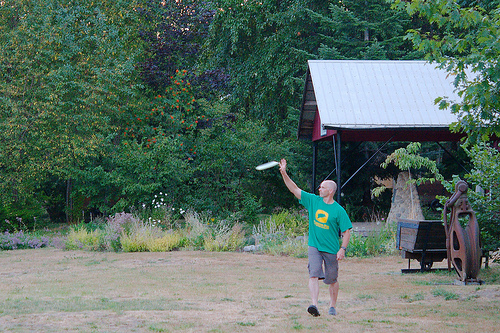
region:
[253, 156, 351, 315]
A man catching a frisbee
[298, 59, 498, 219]
An old red barn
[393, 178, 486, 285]
A piece of old farm equipment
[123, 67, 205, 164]
a tree with red flowers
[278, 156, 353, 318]
a man in a green shirt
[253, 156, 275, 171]
a white frisbee flying through the air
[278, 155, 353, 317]
a man playing a game of catch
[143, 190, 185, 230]
a bush with white flowers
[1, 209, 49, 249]
a bush with purple flowers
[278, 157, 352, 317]
a man playing a game in a field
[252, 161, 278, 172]
White frisbee in the air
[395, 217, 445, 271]
Old wooden cart with metal trim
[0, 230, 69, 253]
Purple flowers on the ground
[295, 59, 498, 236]
Large shed in the background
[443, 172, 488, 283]
Old rusted metal wheel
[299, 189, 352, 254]
Green t-shirt with yellow print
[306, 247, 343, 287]
Grey shorts on a man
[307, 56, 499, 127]
White metal roof on a shed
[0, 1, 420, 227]
Tall trees in the background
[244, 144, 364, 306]
man catching a frisbee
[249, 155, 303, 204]
the frisbee is white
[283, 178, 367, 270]
shirt is green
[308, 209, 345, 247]
letters are yellow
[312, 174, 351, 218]
man has no hair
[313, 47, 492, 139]
roof is white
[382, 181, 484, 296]
old trailer made of wood and iron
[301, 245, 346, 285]
the mans shorts are gray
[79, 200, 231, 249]
tall grass behind the man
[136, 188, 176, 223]
white flowers on the grass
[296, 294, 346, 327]
man is wearing shoes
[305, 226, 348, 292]
man is wearing gray shorts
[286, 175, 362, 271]
the man is wearing a green shirt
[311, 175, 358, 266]
man is bald and wearing a watch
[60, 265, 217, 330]
grass is short and brown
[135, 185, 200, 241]
flowers are white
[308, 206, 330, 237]
lettering is yellow on shirt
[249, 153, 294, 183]
frisbee is white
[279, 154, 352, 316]
Man waving as he walks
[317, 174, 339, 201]
Man has shaved head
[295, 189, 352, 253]
Man wearing green shirt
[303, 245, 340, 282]
Man wearing grey shorts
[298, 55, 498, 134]
Metal roof on building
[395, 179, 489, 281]
Metal object for decoration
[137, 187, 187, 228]
White flowers near the bushes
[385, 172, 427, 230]
Object made of stone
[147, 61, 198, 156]
Bushes with orange leaves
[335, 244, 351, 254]
Man wearing a watch